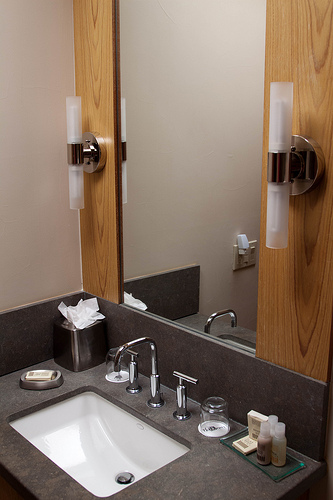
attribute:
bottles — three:
[251, 411, 293, 469]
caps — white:
[257, 419, 285, 434]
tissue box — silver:
[53, 299, 108, 371]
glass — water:
[195, 392, 230, 437]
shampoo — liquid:
[274, 420, 286, 467]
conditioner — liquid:
[256, 421, 270, 463]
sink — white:
[10, 385, 191, 498]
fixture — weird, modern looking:
[170, 369, 198, 421]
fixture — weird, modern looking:
[124, 349, 142, 394]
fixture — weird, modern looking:
[112, 335, 164, 407]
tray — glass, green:
[225, 421, 306, 484]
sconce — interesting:
[264, 81, 287, 250]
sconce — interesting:
[64, 95, 85, 209]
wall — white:
[1, 6, 95, 346]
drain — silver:
[113, 467, 137, 486]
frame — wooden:
[98, 0, 122, 303]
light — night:
[231, 233, 254, 261]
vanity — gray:
[9, 358, 270, 497]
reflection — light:
[67, 326, 92, 370]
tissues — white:
[59, 298, 105, 321]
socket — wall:
[233, 241, 248, 268]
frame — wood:
[69, 16, 319, 356]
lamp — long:
[256, 71, 320, 258]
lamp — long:
[59, 90, 109, 213]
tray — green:
[224, 422, 311, 481]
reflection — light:
[44, 430, 97, 463]